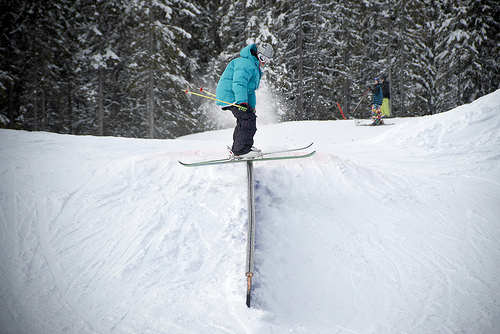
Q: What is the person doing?
A: Skiing.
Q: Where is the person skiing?
A: Snow covered hill.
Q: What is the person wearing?
A: Blue coat.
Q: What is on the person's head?
A: Hat.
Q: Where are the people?
A: In the snow.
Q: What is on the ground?
A: Snow.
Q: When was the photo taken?
A: Winter time.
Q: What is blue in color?
A: The coat.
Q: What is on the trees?
A: Snow.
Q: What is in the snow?
A: Tracks.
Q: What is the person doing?
A: Grinding.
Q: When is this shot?
A: Daytime.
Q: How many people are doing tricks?
A: 1.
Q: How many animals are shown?
A: 0.